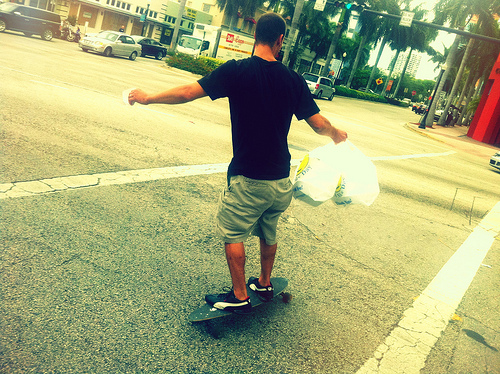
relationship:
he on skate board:
[129, 11, 348, 318] [187, 274, 292, 333]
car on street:
[74, 27, 144, 59] [3, 29, 495, 372]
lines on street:
[348, 195, 497, 371] [3, 29, 495, 372]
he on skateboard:
[120, 8, 350, 315] [189, 271, 292, 336]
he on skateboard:
[129, 11, 348, 318] [146, 262, 306, 322]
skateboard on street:
[189, 271, 295, 336] [44, 135, 463, 347]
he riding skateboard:
[129, 11, 348, 318] [187, 273, 291, 324]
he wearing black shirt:
[129, 11, 348, 318] [194, 52, 319, 182]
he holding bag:
[129, 11, 348, 318] [332, 133, 383, 208]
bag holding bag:
[332, 133, 383, 208] [290, 133, 342, 205]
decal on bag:
[287, 146, 360, 214] [290, 133, 342, 205]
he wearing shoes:
[129, 11, 348, 318] [203, 275, 275, 315]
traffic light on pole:
[341, 0, 361, 22] [346, 2, 499, 44]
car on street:
[306, 74, 335, 100] [3, 29, 495, 372]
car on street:
[132, 35, 167, 58] [3, 29, 495, 372]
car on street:
[78, 29, 143, 59] [3, 29, 495, 372]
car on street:
[0, 1, 63, 41] [3, 29, 495, 372]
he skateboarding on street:
[129, 11, 348, 318] [293, 90, 498, 372]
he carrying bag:
[129, 11, 348, 318] [333, 141, 379, 205]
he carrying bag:
[129, 11, 348, 318] [291, 139, 337, 207]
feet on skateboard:
[215, 282, 298, 323] [180, 272, 290, 331]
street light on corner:
[405, 38, 470, 133] [381, 87, 471, 189]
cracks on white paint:
[1, 170, 137, 198] [0, 145, 463, 197]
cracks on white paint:
[355, 296, 455, 371] [348, 197, 495, 372]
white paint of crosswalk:
[0, 145, 463, 197] [0, 147, 499, 369]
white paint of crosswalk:
[348, 197, 495, 372] [0, 147, 499, 369]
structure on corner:
[435, 47, 499, 142] [407, 121, 474, 147]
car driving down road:
[78, 29, 143, 59] [10, 55, 110, 70]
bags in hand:
[295, 143, 382, 210] [326, 128, 349, 144]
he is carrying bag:
[129, 11, 348, 318] [332, 133, 383, 208]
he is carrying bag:
[129, 11, 348, 318] [290, 133, 342, 205]